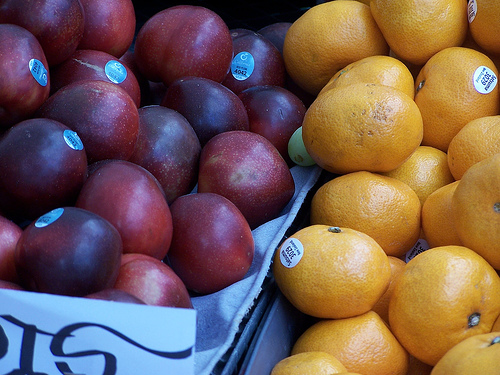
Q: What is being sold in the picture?
A: Fruit.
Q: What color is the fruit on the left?
A: Purple.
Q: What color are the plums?
A: Purple.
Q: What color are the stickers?
A: White.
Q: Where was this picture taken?
A: Farmer's Market.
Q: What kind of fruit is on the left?
A: Plums.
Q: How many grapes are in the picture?
A: One.